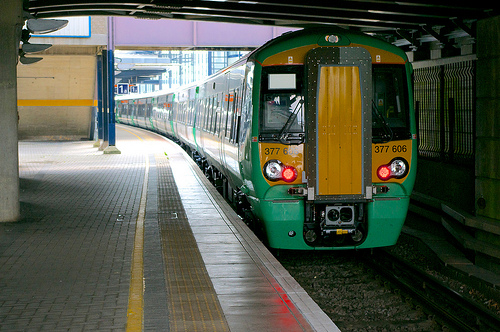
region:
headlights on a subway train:
[261, 152, 427, 195]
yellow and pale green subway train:
[223, 32, 429, 261]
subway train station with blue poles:
[79, 14, 285, 169]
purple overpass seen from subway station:
[100, 8, 313, 67]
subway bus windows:
[125, 83, 272, 131]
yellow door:
[299, 45, 379, 208]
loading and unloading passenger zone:
[11, 84, 233, 328]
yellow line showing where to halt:
[110, 102, 157, 324]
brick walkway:
[16, 128, 129, 311]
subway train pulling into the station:
[61, 15, 419, 315]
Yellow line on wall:
[14, 95, 102, 109]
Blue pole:
[105, 46, 122, 147]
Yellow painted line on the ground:
[113, 121, 156, 329]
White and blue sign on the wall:
[23, 15, 100, 40]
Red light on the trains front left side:
[277, 163, 298, 183]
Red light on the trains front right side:
[375, 160, 390, 176]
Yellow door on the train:
[315, 60, 365, 195]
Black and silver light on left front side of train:
[260, 160, 280, 180]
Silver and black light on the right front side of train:
[386, 151, 412, 179]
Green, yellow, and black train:
[115, 26, 418, 251]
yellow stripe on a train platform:
[132, 138, 169, 327]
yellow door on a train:
[286, 40, 378, 205]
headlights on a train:
[248, 149, 305, 191]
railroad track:
[356, 255, 428, 322]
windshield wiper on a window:
[266, 90, 320, 150]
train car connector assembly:
[306, 195, 391, 250]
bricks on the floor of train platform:
[63, 164, 135, 283]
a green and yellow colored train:
[119, 54, 421, 208]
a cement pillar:
[0, 10, 39, 228]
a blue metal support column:
[93, 42, 128, 153]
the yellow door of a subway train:
[299, 42, 390, 212]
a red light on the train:
[280, 162, 297, 185]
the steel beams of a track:
[350, 228, 488, 326]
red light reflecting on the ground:
[259, 273, 318, 319]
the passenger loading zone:
[21, 124, 261, 320]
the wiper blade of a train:
[277, 92, 312, 142]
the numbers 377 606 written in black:
[372, 140, 415, 157]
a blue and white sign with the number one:
[113, 75, 132, 100]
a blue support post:
[103, 43, 128, 159]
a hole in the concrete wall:
[473, 194, 490, 219]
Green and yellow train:
[116, 25, 432, 262]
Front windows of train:
[263, 65, 416, 145]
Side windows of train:
[113, 96, 242, 131]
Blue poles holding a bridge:
[86, 43, 133, 155]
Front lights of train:
[263, 152, 409, 187]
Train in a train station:
[15, 7, 494, 322]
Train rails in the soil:
[295, 244, 491, 326]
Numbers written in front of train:
[256, 137, 411, 167]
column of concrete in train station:
[0, 3, 27, 229]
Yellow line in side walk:
[123, 123, 154, 330]